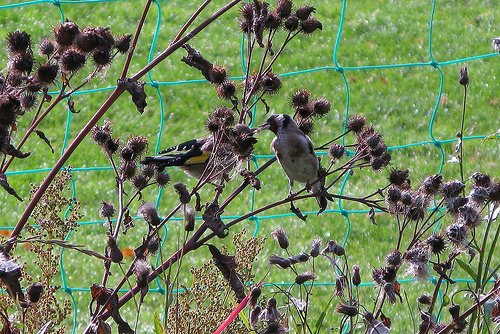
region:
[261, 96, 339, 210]
bird siting on branch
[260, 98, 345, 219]
small bird on branch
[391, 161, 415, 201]
purple flower on plant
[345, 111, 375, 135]
purple flower on plant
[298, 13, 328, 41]
purple flower on plant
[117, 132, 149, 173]
purple flower on plant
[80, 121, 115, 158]
purple flower on plant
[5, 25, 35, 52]
purple flower on plant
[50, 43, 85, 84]
purple flower on plant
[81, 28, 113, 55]
purple flower on plant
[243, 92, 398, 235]
bird standing on branch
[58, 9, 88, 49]
grey bird on branch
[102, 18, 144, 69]
small prickly purple ball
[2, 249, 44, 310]
small prickly purple ball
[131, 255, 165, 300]
small prickly purple ball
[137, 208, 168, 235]
small prickly purple ball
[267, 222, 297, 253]
small prickly purple ball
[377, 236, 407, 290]
small prickly purple ball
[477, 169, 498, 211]
small prickly purple ball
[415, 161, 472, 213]
small prickly purple ball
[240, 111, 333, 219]
bird on the fence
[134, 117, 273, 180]
yellow bird on the fence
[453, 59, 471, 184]
thin flower growing by the fence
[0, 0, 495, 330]
light blue fence with flowers around it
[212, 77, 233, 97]
balls on the flowers by the fence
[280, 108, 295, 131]
black spot on the bird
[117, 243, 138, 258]
orange leaf on the grass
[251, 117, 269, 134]
bird's beak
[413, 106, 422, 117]
little white thing growing in the grass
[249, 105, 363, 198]
this is a bird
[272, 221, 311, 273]
this is a flower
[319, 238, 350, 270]
this is a flower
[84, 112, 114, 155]
this is a flower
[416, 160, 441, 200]
this is a flower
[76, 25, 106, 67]
this is a flower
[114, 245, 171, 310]
this is a flower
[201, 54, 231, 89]
this is a flower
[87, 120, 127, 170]
this is a flower